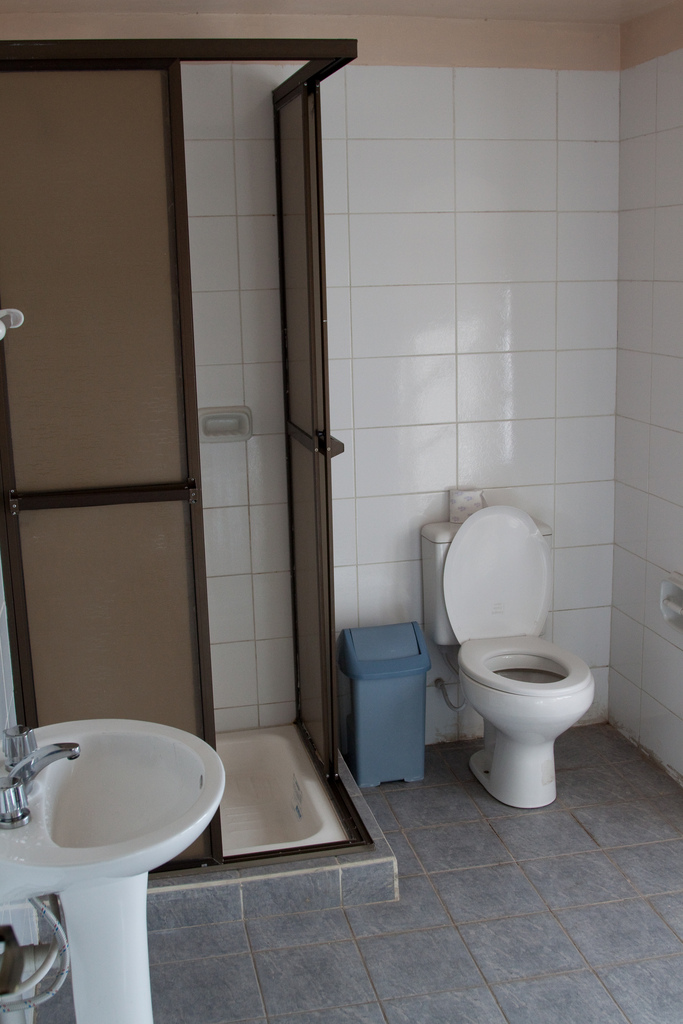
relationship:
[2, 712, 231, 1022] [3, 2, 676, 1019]
sink in bathroom